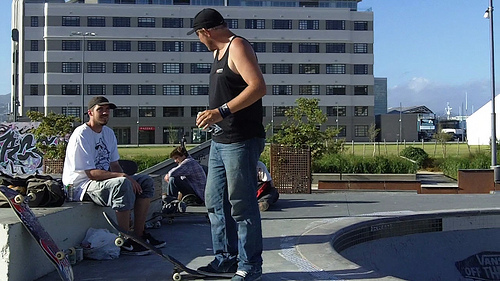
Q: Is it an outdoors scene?
A: Yes, it is outdoors.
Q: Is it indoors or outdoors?
A: It is outdoors.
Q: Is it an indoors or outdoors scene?
A: It is outdoors.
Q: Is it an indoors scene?
A: No, it is outdoors.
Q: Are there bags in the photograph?
A: Yes, there is a bag.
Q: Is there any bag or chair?
A: Yes, there is a bag.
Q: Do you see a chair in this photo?
A: No, there are no chairs.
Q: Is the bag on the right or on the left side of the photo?
A: The bag is on the left of the image.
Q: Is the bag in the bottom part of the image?
A: Yes, the bag is in the bottom of the image.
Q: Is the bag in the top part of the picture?
A: No, the bag is in the bottom of the image.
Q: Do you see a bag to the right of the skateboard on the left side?
A: Yes, there is a bag to the right of the skateboard.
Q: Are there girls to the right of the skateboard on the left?
A: No, there is a bag to the right of the skateboard.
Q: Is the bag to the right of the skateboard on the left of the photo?
A: Yes, the bag is to the right of the skateboard.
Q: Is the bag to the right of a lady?
A: No, the bag is to the right of the skateboard.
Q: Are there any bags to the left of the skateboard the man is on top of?
A: Yes, there is a bag to the left of the skateboard.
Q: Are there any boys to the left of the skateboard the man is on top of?
A: No, there is a bag to the left of the skateboard.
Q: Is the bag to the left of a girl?
A: No, the bag is to the left of a skateboard.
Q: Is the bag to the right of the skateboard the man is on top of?
A: No, the bag is to the left of the skateboard.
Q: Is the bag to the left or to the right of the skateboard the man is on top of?
A: The bag is to the left of the skateboard.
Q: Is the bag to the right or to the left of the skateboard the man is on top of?
A: The bag is to the left of the skateboard.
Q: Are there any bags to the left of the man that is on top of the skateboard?
A: Yes, there is a bag to the left of the man.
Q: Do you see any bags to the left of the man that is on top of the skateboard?
A: Yes, there is a bag to the left of the man.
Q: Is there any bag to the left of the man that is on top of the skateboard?
A: Yes, there is a bag to the left of the man.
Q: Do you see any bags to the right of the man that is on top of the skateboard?
A: No, the bag is to the left of the man.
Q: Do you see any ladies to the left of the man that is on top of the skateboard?
A: No, there is a bag to the left of the man.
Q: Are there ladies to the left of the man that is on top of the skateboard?
A: No, there is a bag to the left of the man.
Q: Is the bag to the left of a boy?
A: No, the bag is to the left of the man.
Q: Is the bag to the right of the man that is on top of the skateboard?
A: No, the bag is to the left of the man.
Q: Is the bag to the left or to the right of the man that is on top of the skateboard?
A: The bag is to the left of the man.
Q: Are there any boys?
A: No, there are no boys.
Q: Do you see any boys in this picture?
A: No, there are no boys.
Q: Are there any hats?
A: Yes, there is a hat.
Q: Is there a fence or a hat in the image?
A: Yes, there is a hat.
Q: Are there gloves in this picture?
A: No, there are no gloves.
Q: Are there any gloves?
A: No, there are no gloves.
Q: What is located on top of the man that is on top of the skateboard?
A: The hat is on top of the man.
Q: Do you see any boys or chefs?
A: No, there are no boys or chefs.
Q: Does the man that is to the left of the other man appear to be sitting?
A: Yes, the man is sitting.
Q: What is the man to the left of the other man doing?
A: The man is sitting.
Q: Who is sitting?
A: The man is sitting.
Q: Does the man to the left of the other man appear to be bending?
A: No, the man is sitting.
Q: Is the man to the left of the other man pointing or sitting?
A: The man is sitting.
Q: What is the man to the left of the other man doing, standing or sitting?
A: The man is sitting.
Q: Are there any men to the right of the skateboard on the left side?
A: Yes, there is a man to the right of the skateboard.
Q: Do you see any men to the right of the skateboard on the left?
A: Yes, there is a man to the right of the skateboard.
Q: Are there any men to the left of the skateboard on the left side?
A: No, the man is to the right of the skateboard.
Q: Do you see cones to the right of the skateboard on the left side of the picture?
A: No, there is a man to the right of the skateboard.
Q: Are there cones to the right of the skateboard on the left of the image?
A: No, there is a man to the right of the skateboard.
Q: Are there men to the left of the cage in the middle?
A: Yes, there is a man to the left of the cage.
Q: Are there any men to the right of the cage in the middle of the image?
A: No, the man is to the left of the cage.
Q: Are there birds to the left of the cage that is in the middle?
A: No, there is a man to the left of the cage.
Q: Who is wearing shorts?
A: The man is wearing shorts.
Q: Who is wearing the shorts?
A: The man is wearing shorts.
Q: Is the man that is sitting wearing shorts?
A: Yes, the man is wearing shorts.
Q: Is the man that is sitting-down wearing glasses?
A: No, the man is wearing shorts.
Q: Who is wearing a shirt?
A: The man is wearing a shirt.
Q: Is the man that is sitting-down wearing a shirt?
A: Yes, the man is wearing a shirt.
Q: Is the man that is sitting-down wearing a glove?
A: No, the man is wearing a shirt.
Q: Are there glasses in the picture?
A: No, there are no glasses.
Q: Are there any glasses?
A: No, there are no glasses.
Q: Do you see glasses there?
A: No, there are no glasses.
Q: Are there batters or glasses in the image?
A: No, there are no glasses or batters.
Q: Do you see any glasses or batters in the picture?
A: No, there are no glasses or batters.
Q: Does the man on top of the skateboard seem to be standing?
A: Yes, the man is standing.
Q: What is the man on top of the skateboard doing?
A: The man is standing.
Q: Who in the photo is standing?
A: The man is standing.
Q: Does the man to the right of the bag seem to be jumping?
A: No, the man is standing.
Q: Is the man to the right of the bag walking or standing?
A: The man is standing.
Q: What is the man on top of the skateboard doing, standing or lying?
A: The man is standing.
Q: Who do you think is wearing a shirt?
A: The man is wearing a shirt.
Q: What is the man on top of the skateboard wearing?
A: The man is wearing a shirt.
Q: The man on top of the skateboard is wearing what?
A: The man is wearing a shirt.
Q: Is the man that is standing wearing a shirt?
A: Yes, the man is wearing a shirt.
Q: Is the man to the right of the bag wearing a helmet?
A: No, the man is wearing a shirt.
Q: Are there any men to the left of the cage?
A: Yes, there is a man to the left of the cage.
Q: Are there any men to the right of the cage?
A: No, the man is to the left of the cage.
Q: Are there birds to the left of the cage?
A: No, there is a man to the left of the cage.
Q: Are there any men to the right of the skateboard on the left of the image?
A: Yes, there is a man to the right of the skateboard.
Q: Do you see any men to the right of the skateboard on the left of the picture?
A: Yes, there is a man to the right of the skateboard.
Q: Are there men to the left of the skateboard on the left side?
A: No, the man is to the right of the skateboard.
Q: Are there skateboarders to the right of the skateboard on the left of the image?
A: No, there is a man to the right of the skateboard.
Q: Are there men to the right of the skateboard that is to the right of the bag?
A: Yes, there is a man to the right of the skateboard.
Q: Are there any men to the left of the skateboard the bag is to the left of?
A: No, the man is to the right of the skateboard.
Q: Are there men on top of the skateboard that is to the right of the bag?
A: Yes, there is a man on top of the skateboard.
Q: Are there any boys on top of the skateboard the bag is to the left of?
A: No, there is a man on top of the skateboard.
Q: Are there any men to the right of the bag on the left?
A: Yes, there is a man to the right of the bag.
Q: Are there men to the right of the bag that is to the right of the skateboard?
A: Yes, there is a man to the right of the bag.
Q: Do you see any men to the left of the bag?
A: No, the man is to the right of the bag.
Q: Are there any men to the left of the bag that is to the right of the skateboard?
A: No, the man is to the right of the bag.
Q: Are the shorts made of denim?
A: Yes, the shorts are made of denim.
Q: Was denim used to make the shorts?
A: Yes, the shorts are made of denim.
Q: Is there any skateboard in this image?
A: Yes, there is a skateboard.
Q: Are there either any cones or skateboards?
A: Yes, there is a skateboard.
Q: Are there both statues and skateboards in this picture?
A: No, there is a skateboard but no statues.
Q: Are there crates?
A: No, there are no crates.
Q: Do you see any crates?
A: No, there are no crates.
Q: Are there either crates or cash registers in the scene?
A: No, there are no crates or cash registers.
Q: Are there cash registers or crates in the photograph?
A: No, there are no crates or cash registers.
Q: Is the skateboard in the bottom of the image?
A: Yes, the skateboard is in the bottom of the image.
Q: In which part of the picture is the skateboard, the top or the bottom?
A: The skateboard is in the bottom of the image.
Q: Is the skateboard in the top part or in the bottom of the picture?
A: The skateboard is in the bottom of the image.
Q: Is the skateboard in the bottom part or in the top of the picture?
A: The skateboard is in the bottom of the image.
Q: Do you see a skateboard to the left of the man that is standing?
A: Yes, there is a skateboard to the left of the man.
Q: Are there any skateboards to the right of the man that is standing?
A: No, the skateboard is to the left of the man.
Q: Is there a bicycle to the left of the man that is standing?
A: No, there is a skateboard to the left of the man.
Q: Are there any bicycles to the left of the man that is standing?
A: No, there is a skateboard to the left of the man.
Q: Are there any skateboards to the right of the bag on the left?
A: Yes, there is a skateboard to the right of the bag.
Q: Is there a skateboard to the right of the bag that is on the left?
A: Yes, there is a skateboard to the right of the bag.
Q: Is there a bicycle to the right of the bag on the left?
A: No, there is a skateboard to the right of the bag.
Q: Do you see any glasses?
A: No, there are no glasses.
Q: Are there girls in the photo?
A: No, there are no girls.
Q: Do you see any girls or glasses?
A: No, there are no girls or glasses.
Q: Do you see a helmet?
A: No, there are no helmets.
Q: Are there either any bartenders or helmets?
A: No, there are no helmets or bartenders.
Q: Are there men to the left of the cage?
A: Yes, there is a man to the left of the cage.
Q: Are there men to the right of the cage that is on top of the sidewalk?
A: No, the man is to the left of the cage.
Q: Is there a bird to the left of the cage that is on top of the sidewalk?
A: No, there is a man to the left of the cage.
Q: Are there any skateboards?
A: Yes, there is a skateboard.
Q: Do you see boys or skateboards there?
A: Yes, there is a skateboard.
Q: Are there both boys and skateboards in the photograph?
A: No, there is a skateboard but no boys.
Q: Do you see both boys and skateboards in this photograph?
A: No, there is a skateboard but no boys.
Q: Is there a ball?
A: No, there are no balls.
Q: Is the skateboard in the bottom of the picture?
A: Yes, the skateboard is in the bottom of the image.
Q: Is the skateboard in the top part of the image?
A: No, the skateboard is in the bottom of the image.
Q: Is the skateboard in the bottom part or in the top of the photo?
A: The skateboard is in the bottom of the image.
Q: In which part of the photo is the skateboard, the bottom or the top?
A: The skateboard is in the bottom of the image.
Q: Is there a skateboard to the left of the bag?
A: Yes, there is a skateboard to the left of the bag.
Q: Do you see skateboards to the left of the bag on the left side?
A: Yes, there is a skateboard to the left of the bag.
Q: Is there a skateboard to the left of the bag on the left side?
A: Yes, there is a skateboard to the left of the bag.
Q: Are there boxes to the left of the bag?
A: No, there is a skateboard to the left of the bag.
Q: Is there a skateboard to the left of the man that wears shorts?
A: Yes, there is a skateboard to the left of the man.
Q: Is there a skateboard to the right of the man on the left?
A: No, the skateboard is to the left of the man.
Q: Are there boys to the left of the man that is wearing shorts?
A: No, there is a skateboard to the left of the man.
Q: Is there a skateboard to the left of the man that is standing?
A: Yes, there is a skateboard to the left of the man.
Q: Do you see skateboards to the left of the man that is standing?
A: Yes, there is a skateboard to the left of the man.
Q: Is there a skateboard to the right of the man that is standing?
A: No, the skateboard is to the left of the man.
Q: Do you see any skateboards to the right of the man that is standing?
A: No, the skateboard is to the left of the man.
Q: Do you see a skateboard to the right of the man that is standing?
A: No, the skateboard is to the left of the man.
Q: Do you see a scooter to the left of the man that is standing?
A: No, there is a skateboard to the left of the man.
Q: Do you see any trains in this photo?
A: No, there are no trains.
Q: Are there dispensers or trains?
A: No, there are no trains or dispensers.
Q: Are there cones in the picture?
A: No, there are no cones.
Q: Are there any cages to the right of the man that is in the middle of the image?
A: Yes, there is a cage to the right of the man.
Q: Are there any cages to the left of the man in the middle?
A: No, the cage is to the right of the man.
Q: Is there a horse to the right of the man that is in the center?
A: No, there is a cage to the right of the man.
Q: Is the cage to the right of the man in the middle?
A: Yes, the cage is to the right of the man.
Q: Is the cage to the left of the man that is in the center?
A: No, the cage is to the right of the man.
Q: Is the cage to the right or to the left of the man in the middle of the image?
A: The cage is to the right of the man.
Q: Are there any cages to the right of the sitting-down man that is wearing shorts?
A: Yes, there is a cage to the right of the man.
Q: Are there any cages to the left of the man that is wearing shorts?
A: No, the cage is to the right of the man.